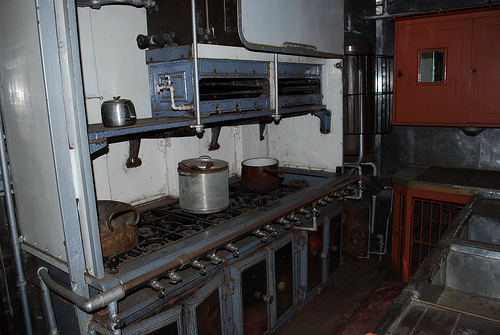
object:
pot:
[100, 90, 140, 130]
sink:
[408, 208, 499, 325]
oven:
[136, 45, 276, 133]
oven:
[272, 55, 344, 115]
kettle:
[95, 86, 149, 137]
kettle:
[236, 152, 288, 194]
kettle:
[166, 148, 238, 222]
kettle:
[93, 190, 147, 262]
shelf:
[82, 111, 209, 152]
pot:
[176, 153, 232, 215]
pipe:
[25, 269, 137, 314]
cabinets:
[118, 235, 353, 333]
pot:
[239, 155, 283, 191]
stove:
[101, 117, 352, 314]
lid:
[178, 152, 228, 169]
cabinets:
[325, 215, 347, 278]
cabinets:
[294, 222, 329, 297]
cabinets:
[269, 232, 299, 324]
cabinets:
[232, 252, 274, 334]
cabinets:
[189, 275, 226, 333]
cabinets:
[124, 301, 188, 333]